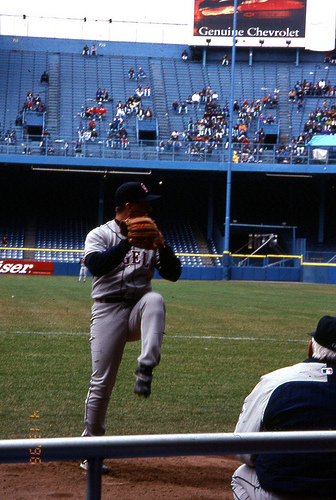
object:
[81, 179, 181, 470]
man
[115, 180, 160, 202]
hat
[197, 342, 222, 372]
grass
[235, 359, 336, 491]
jacket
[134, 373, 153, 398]
sneakers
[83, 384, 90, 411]
stripe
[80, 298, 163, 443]
pants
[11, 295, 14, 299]
ball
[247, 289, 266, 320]
grass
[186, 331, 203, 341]
line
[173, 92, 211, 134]
people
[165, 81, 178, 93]
bench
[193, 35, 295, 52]
lights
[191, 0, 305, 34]
screen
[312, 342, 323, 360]
hair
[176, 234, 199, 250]
chairs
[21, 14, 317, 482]
scene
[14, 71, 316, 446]
photo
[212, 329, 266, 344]
line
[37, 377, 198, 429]
ground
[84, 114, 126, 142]
people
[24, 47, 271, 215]
stadium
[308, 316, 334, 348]
cap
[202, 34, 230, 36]
billboard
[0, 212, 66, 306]
stadium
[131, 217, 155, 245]
ball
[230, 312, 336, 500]
man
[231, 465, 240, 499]
knees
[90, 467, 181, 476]
mound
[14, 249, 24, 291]
part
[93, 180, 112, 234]
stands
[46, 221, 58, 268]
level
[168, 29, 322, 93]
stadium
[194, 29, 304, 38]
advertisement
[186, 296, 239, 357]
field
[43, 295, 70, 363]
field